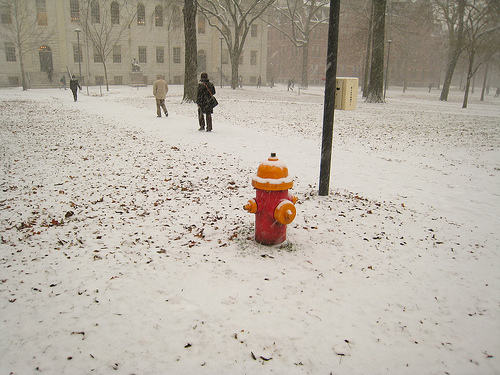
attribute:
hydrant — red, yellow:
[244, 153, 297, 248]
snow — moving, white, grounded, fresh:
[1, 83, 499, 374]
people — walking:
[71, 73, 218, 131]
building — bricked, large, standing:
[0, 3, 271, 87]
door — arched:
[39, 45, 55, 83]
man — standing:
[198, 71, 217, 132]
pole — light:
[381, 38, 391, 102]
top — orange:
[251, 151, 295, 192]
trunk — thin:
[103, 62, 110, 90]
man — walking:
[153, 73, 170, 117]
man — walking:
[69, 74, 83, 100]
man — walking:
[257, 74, 262, 90]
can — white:
[333, 76, 359, 110]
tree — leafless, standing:
[198, 2, 276, 89]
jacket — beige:
[152, 81, 169, 100]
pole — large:
[319, 0, 340, 195]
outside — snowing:
[0, 1, 499, 373]